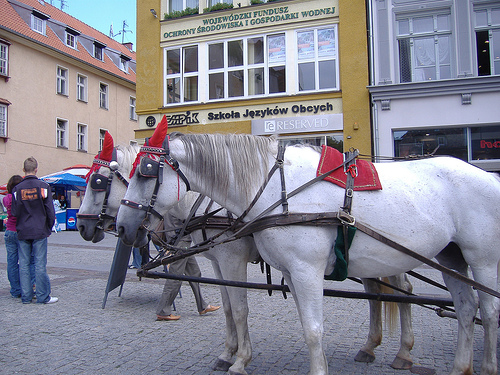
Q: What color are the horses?
A: White.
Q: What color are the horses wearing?
A: Red.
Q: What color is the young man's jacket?
A: Blue and orange.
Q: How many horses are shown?
A: 2.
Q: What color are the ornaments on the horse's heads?
A: Red.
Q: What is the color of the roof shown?
A: Orange.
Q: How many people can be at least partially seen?
A: 4.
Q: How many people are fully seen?
A: 2.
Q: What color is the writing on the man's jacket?
A: Orange.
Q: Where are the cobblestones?
A: On the street.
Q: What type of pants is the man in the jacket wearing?
A: Jeans.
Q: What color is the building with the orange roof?
A: Peach.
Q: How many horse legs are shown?
A: 8.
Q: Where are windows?
A: On buildings.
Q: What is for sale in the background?
A: Pepsi.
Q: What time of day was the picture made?
A: Daytime.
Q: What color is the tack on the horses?
A: Black.